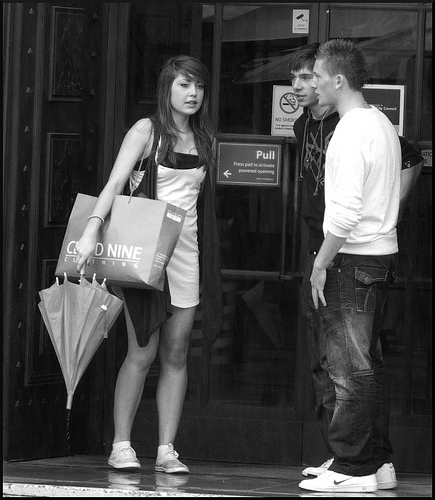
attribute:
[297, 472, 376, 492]
sneaker — white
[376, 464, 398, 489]
sneaker — white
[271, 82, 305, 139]
sign — no smoking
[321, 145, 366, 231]
sleeve — pushed up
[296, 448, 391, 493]
nike shoes — white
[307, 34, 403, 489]
boy — young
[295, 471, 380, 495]
sneaker — white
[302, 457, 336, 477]
sneaker — white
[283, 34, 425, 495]
men — young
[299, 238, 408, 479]
jeans — blue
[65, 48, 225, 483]
women — shopping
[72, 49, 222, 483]
woman — young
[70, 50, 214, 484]
girl — young